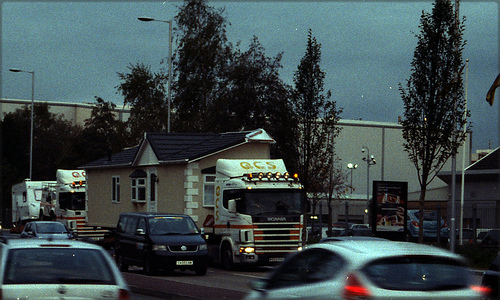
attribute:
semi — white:
[207, 158, 308, 273]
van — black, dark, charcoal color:
[112, 212, 208, 279]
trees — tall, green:
[0, 1, 471, 237]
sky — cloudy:
[0, 1, 499, 153]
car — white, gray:
[242, 239, 487, 299]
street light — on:
[136, 17, 170, 30]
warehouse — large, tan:
[0, 98, 470, 231]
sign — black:
[373, 179, 408, 236]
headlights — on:
[239, 247, 304, 255]